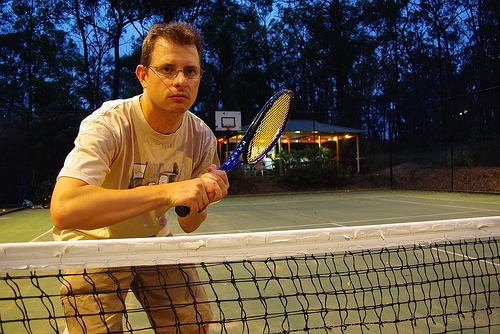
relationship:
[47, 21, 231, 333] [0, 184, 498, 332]
man playing tennis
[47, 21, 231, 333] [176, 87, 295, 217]
man holding tennis racket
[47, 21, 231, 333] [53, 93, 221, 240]
man wearing a shirt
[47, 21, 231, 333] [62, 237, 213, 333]
man wearing shorts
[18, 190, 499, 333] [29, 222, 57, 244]
court has paint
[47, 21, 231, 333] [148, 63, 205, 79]
man wearing glasses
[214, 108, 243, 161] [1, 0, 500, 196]
basketball goal in background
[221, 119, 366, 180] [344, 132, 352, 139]
tent has a light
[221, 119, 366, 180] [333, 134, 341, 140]
tent has a light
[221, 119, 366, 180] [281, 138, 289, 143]
tent has a light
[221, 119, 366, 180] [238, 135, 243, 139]
tent has a light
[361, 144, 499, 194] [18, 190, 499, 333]
fence around court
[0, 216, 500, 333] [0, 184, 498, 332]
net for tennis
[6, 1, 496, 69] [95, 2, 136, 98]
sky behind tree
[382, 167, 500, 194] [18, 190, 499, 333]
ground by court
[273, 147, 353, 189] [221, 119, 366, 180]
bushes are by tent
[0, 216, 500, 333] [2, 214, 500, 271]
net has a white top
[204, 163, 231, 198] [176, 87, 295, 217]
hand holding tennis racket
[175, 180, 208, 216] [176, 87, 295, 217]
hand holding tennis racket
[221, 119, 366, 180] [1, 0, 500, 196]
tent in background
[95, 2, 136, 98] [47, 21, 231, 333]
tree behind man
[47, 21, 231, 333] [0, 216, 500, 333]
man behind net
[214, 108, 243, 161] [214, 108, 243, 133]
basketball goal has a backboard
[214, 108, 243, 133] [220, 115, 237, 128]
backboard has a box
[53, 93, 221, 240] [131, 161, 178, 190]
shirt has a design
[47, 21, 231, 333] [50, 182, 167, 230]
man has a forearm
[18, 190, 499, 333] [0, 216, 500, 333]
court has a net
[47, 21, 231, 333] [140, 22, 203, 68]
man has hair